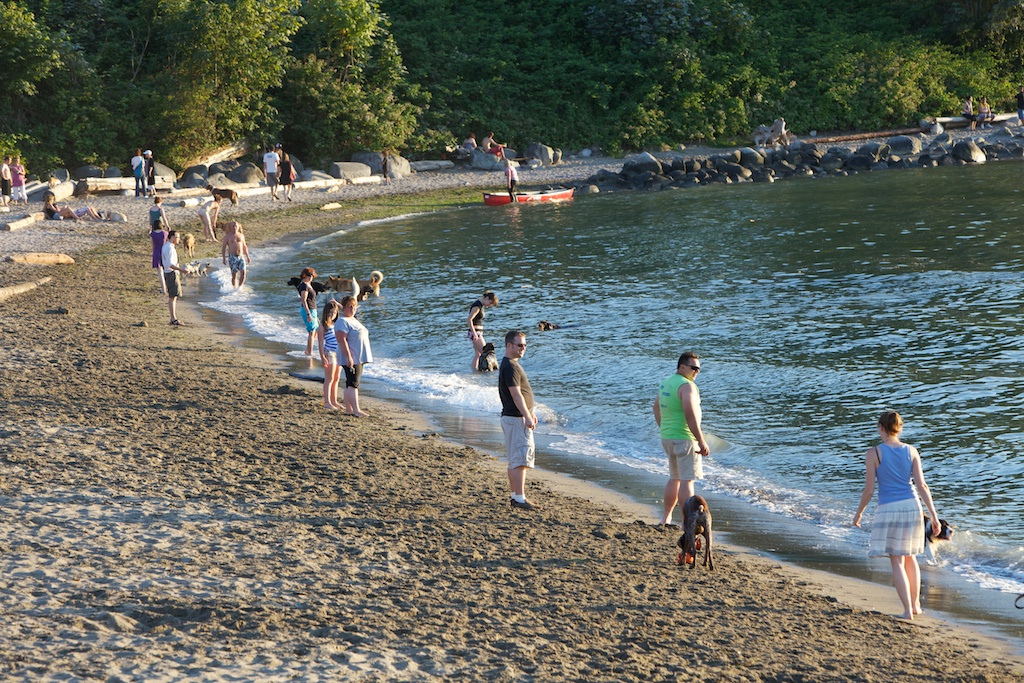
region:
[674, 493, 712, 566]
a dog on the beach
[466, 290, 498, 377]
a couple of kids in the water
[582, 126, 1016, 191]
a row of large rocks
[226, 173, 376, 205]
a row of logs on the beach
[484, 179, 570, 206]
a red boat in the water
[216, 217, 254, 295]
a shirtless man wading in the water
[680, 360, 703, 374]
sunglasses on a man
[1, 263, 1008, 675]
a beach covered with footprints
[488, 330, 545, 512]
A man in a black shirt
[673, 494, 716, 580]
A dog on the beach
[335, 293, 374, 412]
A lady with black pants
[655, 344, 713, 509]
Man in green shirt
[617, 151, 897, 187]
Rocks on the shore of the beach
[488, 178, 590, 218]
A small red boat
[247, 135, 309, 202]
A couple walking on the beach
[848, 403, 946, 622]
person standing on the beach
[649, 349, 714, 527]
person standing on the beach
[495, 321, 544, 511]
person standing on the beach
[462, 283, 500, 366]
person standing on the beach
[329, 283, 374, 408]
person standing on the beach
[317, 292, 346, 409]
person standing on the beach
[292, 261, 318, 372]
person standing on the beach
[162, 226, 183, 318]
person standing on the beach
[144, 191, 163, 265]
person standing on the beach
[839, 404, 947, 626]
woman walking along beach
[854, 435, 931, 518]
woman's tank top is blue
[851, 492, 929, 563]
woman wearing a skirt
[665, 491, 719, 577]
dog walking along beach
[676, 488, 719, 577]
dog is mostly black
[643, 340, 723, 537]
man standing in front of water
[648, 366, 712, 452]
man's shirt is green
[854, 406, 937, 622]
woman wearing blue shirt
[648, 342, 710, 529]
man wearing green shirt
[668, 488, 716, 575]
brown dog with toy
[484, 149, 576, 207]
person in red boat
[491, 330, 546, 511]
man wearing sunglasses and black shirt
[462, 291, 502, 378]
child standing in water with black vest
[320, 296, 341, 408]
child wearing blue striped swimsuit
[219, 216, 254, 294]
man walking with no shirt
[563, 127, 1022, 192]
rocky outcrop along water's edge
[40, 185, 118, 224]
person relaxing on sand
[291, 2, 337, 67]
green leaves on the tree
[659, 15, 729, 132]
green leaves on the tree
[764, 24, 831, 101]
green leaves on the tree